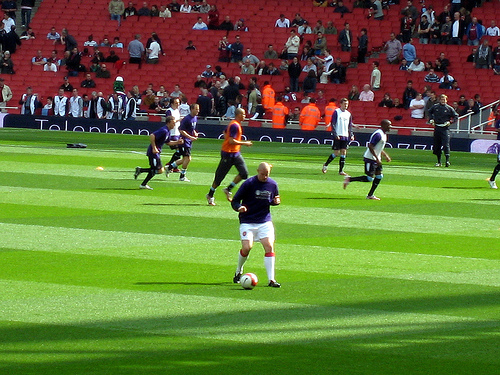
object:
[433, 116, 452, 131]
waist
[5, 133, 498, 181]
line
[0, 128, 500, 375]
grass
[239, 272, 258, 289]
soccer ball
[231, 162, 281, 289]
man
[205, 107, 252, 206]
men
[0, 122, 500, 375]
field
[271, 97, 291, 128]
man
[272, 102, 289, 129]
coat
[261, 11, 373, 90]
people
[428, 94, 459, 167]
man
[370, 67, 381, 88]
shirt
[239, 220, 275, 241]
shorts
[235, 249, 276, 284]
socks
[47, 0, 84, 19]
seats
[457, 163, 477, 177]
line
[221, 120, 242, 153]
vest